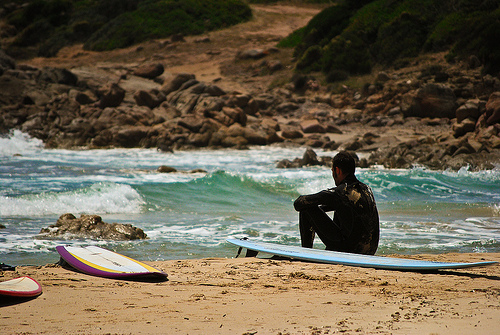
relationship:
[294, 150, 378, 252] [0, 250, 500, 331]
man sitting on beach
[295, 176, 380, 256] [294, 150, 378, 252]
wetsuit on man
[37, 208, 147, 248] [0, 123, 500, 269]
rock in water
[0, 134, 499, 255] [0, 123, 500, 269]
water in water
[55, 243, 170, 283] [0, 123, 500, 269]
boogie board lying next to water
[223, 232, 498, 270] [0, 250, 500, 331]
surfboard laying on beach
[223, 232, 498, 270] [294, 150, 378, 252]
surfboard beside man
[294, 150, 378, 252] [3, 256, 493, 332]
man sitting on beach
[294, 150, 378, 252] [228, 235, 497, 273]
man sitting next to surfboard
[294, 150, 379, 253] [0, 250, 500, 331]
surfer sitting on beach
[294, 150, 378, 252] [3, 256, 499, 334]
man sitting on beach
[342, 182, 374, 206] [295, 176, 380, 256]
sand on wetsuit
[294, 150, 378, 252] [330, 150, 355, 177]
man has hair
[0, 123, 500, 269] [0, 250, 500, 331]
water near beach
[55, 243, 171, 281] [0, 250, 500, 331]
boogie board on beach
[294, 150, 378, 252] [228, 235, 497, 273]
man sitting beside surfboard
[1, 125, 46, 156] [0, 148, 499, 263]
spray on ocean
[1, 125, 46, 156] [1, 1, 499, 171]
spray on shore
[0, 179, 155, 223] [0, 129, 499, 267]
wave in ocean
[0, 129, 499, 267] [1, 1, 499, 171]
ocean near shore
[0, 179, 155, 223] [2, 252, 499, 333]
wave near shore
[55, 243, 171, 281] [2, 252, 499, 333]
boogie board on shore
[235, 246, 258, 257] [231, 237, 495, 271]
fin on surfboard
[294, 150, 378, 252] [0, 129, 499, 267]
man facing ocean